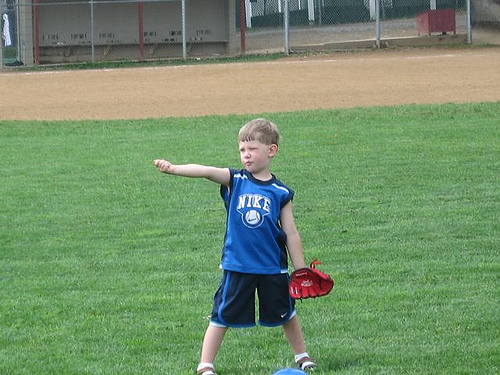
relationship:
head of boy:
[235, 116, 278, 176] [148, 113, 318, 373]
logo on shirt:
[226, 186, 270, 231] [205, 171, 297, 261]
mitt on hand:
[285, 265, 336, 303] [273, 265, 341, 297]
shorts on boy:
[208, 270, 298, 325] [148, 113, 318, 373]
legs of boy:
[197, 327, 310, 354] [148, 113, 318, 373]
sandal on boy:
[294, 354, 320, 374] [148, 113, 318, 373]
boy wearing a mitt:
[148, 113, 318, 373] [287, 256, 333, 303]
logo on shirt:
[234, 193, 272, 231] [219, 167, 296, 277]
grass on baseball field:
[1, 98, 499, 373] [3, 47, 499, 372]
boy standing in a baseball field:
[148, 113, 318, 373] [0, 47, 498, 374]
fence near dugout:
[280, 2, 344, 34] [24, 1, 234, 67]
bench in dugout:
[37, 42, 231, 59] [37, 2, 234, 62]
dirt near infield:
[0, 50, 499, 117] [2, 117, 499, 369]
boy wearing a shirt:
[148, 113, 318, 373] [218, 162, 293, 274]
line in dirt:
[6, 48, 457, 73] [2, 49, 498, 124]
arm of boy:
[150, 157, 231, 184] [148, 113, 318, 373]